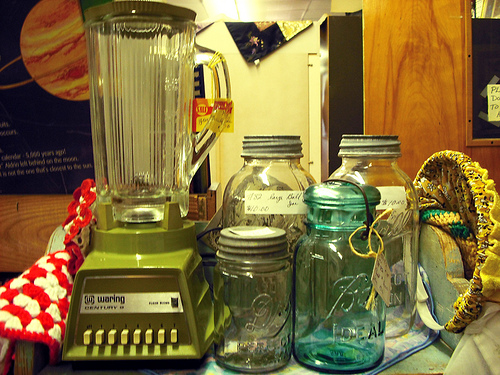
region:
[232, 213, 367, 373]
the gall jars are empty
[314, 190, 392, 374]
the jar is blue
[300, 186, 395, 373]
the jar is covered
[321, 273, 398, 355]
writing is on the jar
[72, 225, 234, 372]
base of the blender is green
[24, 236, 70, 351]
the clothing is red and white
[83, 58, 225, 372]
the blender is old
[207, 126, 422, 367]
the jars are four in total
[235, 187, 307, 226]
there are white stickers on the bottle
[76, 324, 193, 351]
the buttons are white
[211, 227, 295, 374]
Small glass jar used for canning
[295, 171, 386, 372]
Medium sized jar used for canning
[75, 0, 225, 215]
Pitcher for a blender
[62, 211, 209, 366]
Base for a blender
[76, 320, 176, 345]
Buttons to control the blender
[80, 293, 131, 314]
Manufacturer logo on a blender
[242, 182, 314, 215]
Sticker on a canning jar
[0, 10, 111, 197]
Poster on the wall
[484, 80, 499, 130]
Note taped to window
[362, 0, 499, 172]
Wooden door with window in center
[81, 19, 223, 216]
blender on the table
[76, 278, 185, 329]
words on the blender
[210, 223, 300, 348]
glass on the table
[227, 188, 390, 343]
two glasses on the table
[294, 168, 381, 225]
top of the glass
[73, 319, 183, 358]
buttons on the blender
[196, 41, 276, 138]
handle of the blender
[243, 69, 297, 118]
white wall in the background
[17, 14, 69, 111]
planet on a poster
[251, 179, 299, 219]
writing on the jar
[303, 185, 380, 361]
a jar made of clear blue glass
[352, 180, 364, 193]
a white latch on the jar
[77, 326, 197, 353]
white buttons on the base of the blender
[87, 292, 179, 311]
a silver sticker with a logo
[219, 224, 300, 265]
an old metal jar top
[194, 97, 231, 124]
a red and yellow price tag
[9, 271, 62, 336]
a red and white oven mitt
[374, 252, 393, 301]
a white tag with handwriting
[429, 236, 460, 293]
a wooden napkin holder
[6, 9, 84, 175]
a black poster with a planet on it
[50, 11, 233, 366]
green blender with price tag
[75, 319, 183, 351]
buttons on green blender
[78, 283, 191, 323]
silver label on blender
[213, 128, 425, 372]
four glass jars on display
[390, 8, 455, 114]
wood grain on door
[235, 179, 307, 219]
white label on bottle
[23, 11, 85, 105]
orange planet on poster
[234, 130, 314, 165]
metal cover on jar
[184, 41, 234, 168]
handle on glass container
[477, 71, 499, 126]
sign taped to window